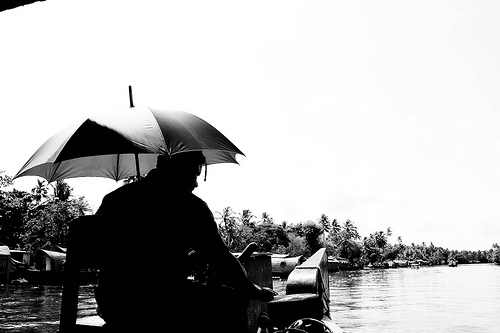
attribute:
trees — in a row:
[3, 169, 499, 275]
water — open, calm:
[329, 261, 499, 330]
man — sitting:
[82, 150, 278, 332]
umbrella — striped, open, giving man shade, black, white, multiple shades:
[10, 83, 246, 183]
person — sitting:
[76, 151, 278, 332]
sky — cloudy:
[0, 1, 500, 247]